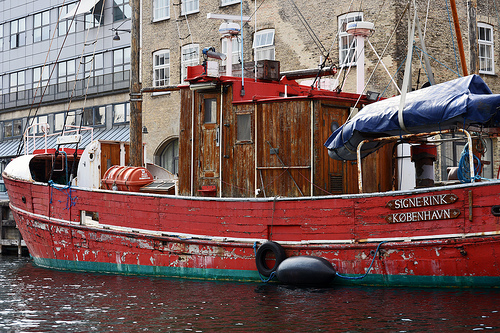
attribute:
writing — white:
[390, 191, 453, 211]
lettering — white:
[389, 206, 455, 224]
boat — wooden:
[0, 58, 499, 270]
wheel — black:
[254, 237, 284, 280]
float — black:
[277, 257, 338, 289]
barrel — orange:
[99, 162, 153, 184]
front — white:
[7, 149, 44, 175]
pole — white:
[349, 39, 371, 95]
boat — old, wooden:
[5, 59, 495, 296]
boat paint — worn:
[3, 185, 494, 277]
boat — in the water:
[2, 46, 471, 296]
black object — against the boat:
[276, 258, 340, 295]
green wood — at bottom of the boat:
[24, 259, 464, 293]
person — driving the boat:
[409, 130, 437, 189]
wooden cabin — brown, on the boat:
[175, 69, 395, 193]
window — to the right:
[339, 10, 367, 64]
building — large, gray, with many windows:
[2, 5, 125, 104]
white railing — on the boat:
[10, 119, 92, 149]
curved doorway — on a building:
[152, 134, 180, 174]